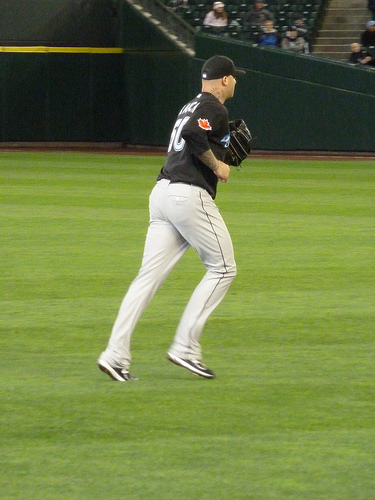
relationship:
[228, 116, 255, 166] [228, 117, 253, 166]
glove on man's hand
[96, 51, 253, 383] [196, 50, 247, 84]
man wearing a hat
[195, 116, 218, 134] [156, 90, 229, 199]
tag on t shirt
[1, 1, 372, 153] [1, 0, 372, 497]
wall near stadium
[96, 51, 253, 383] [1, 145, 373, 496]
man on playing field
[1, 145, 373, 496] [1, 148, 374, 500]
playing field made of grass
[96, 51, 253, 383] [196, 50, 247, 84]
man wearing hat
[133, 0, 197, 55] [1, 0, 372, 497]
stairs are in stadium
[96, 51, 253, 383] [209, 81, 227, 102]
man has a tattoo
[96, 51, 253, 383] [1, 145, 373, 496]
man running on playing field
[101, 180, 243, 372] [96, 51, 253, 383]
pants belong to man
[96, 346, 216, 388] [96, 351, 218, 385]
cleats are on feet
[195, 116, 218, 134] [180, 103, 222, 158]
tag on sleeve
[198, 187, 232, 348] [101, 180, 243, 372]
stripe on pants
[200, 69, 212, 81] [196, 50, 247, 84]
logo on back of hat